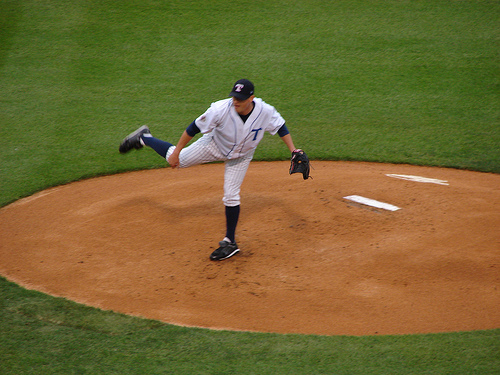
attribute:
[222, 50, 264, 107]
cap — blue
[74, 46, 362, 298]
pitcher — pitching, playing, standing, happening, baseball, stands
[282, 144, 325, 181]
glove — black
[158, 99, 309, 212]
uniform — white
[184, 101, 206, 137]
shirt — blue, t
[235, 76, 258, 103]
hat — blue, t, black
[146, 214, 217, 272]
dirt — red, mound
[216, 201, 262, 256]
sock — black, blue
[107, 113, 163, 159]
shoe — black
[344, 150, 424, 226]
mound — round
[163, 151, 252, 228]
pant — pinstripes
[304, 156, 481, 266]
diamond — baseball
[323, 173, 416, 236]
block — white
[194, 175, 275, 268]
leg — black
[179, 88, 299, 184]
jersey — white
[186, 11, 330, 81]
grass — green